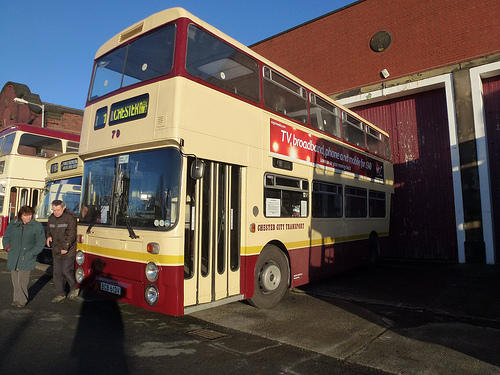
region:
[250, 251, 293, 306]
The wheel of a bus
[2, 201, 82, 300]
Two people walking by the buses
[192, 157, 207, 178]
A side mirror on the bus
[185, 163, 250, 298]
The closed doors of a bus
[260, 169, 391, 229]
Windows on the side of a bus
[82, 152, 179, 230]
The windshield of a bus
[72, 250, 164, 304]
Lights on the front of a bus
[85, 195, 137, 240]
Windshield wipers on the bus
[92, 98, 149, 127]
The display on the top of the bus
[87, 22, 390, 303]
A tall tan and red bus parked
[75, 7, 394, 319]
a tan and red bus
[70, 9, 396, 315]
a double decker bus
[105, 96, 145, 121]
an electronic destination sign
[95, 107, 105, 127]
an electronic destination sign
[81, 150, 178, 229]
a bus front windshield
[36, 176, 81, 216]
a bus front windshield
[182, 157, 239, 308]
a bus entry exit door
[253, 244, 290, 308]
a bus front tire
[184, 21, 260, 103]
a bus passenger window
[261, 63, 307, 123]
a bus passenger window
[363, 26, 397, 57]
circle is on building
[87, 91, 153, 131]
sign has yellow letters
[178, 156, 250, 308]
bus doors are shut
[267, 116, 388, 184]
sign on bus is red and white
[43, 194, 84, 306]
man is next to bus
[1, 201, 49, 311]
woman is wearing a coat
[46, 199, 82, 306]
man is wearing a coat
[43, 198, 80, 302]
man is next to woman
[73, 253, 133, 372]
shadow is on the bus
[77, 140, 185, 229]
bus window is clean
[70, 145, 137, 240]
window of a bus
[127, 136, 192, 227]
window of a bus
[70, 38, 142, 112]
window of a bus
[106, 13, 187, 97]
window of a bus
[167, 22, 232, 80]
window of a bus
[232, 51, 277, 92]
window of a bus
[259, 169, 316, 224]
window of a bus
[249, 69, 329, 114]
window of a bus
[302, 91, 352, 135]
window of a bus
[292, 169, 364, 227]
window of a bus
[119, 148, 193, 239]
window of a bus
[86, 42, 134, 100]
window of a bus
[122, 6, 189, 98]
window of a bus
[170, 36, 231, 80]
window of a bus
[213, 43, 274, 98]
window of a bus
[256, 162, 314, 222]
window of a bus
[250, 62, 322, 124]
window of a bus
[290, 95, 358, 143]
window of a bus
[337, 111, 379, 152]
window of a bus